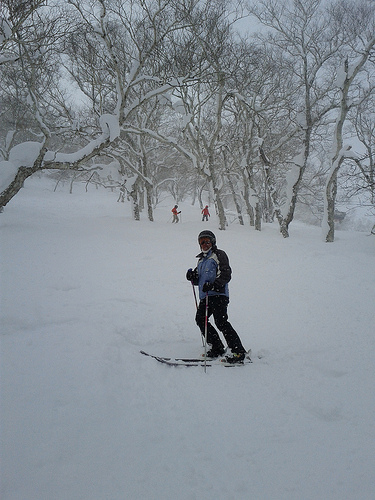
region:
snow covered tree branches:
[8, 9, 146, 184]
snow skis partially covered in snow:
[142, 346, 259, 367]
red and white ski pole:
[202, 281, 215, 357]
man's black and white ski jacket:
[196, 248, 237, 319]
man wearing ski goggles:
[193, 225, 226, 256]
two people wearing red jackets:
[165, 199, 214, 224]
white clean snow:
[9, 221, 128, 466]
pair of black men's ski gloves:
[183, 263, 224, 300]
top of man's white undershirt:
[199, 247, 215, 257]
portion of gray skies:
[63, 75, 82, 108]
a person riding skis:
[139, 228, 274, 369]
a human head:
[193, 226, 224, 251]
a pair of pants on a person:
[181, 300, 247, 374]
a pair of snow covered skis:
[139, 344, 268, 368]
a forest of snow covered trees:
[2, 0, 373, 242]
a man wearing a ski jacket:
[184, 251, 232, 292]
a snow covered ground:
[1, 166, 374, 493]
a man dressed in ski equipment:
[139, 221, 272, 386]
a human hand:
[182, 266, 196, 286]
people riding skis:
[163, 192, 213, 220]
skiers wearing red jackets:
[165, 200, 211, 220]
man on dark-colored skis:
[137, 225, 249, 364]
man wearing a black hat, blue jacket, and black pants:
[186, 228, 246, 363]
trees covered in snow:
[0, 0, 374, 243]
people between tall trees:
[133, 105, 228, 228]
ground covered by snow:
[0, 175, 372, 498]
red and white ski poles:
[189, 279, 209, 371]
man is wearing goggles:
[184, 229, 248, 364]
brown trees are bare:
[2, 3, 373, 240]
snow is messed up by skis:
[5, 285, 374, 498]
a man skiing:
[145, 222, 266, 376]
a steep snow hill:
[40, 167, 267, 490]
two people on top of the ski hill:
[156, 192, 216, 228]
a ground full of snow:
[50, 220, 363, 483]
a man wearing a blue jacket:
[177, 232, 239, 304]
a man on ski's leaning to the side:
[163, 226, 261, 370]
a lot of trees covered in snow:
[14, 18, 354, 192]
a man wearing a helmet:
[182, 221, 232, 263]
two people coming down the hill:
[164, 189, 217, 225]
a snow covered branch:
[38, 109, 137, 174]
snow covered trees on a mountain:
[110, 18, 373, 219]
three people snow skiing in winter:
[150, 187, 261, 373]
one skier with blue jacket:
[167, 226, 257, 377]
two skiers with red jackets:
[160, 198, 210, 222]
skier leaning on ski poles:
[153, 226, 267, 377]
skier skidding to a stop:
[156, 221, 261, 380]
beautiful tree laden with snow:
[0, 31, 185, 212]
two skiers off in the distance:
[154, 187, 231, 237]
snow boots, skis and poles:
[132, 269, 277, 377]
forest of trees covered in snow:
[217, 48, 373, 237]